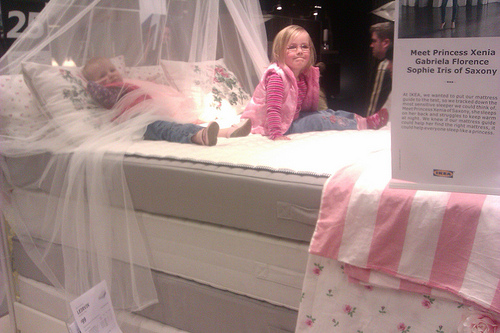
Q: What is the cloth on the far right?
A: A blanket.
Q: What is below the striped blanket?
A: A white blanket with pink flowers.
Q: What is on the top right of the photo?
A: A sign.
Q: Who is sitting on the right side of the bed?
A: A little girl?.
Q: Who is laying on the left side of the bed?
A: A baby girl.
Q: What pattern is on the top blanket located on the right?
A: Stripes.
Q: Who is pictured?
A: Two girls.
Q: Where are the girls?
A: On a mattress.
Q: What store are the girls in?
A: Ikea.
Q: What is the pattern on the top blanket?
A: Light and dark pink stripes.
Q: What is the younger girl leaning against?
A: Pillows.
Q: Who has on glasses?
A: The girl on the right.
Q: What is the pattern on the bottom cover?
A: Floral.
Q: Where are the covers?
A: On top of the mattress.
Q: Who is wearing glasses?
A: The smiling girl.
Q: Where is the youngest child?
A: Lying on the pillow.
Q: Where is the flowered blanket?
A: Under the striped blanket.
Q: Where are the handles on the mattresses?
A: Side of mattresses.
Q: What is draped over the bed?
A: White sheer.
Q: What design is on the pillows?
A: Flowers.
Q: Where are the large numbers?
A: On the wall.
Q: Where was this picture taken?
A: A department store.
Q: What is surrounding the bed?
A: A net.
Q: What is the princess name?
A: Xenia.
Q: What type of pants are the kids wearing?
A: Jeans.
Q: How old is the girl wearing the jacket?
A: 8.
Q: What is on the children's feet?
A: Shoes.